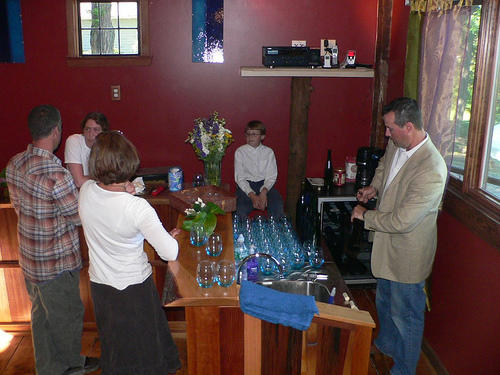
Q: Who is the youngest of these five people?
A: Boy sitting back wall.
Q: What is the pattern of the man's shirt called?
A: Plaid.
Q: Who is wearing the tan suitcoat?
A: Man next to window.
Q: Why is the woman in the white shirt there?
A: Enjoying others.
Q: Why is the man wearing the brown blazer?
A: Looks good.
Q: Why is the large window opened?
A: Fresh air.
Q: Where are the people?
A: In a room.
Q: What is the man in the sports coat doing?
A: Bartending.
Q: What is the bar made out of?
A: Wood.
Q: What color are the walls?
A: Red.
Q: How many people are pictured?
A: Five.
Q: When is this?
A: Daytime.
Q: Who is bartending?
A: The man in the sports coat.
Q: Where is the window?
A: Behind the bartender.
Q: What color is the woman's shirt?
A: White.